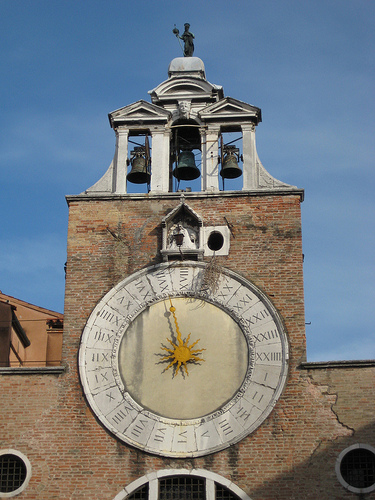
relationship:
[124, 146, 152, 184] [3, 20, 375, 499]
bell on top of building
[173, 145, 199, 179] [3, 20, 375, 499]
bell on top of building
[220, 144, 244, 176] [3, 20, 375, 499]
bell on top of building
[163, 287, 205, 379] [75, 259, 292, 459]
hand on clock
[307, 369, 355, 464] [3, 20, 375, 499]
crack on building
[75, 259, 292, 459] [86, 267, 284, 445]
clock has roman numerals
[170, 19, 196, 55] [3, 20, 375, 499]
statue on top of building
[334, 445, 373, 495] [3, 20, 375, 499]
window in building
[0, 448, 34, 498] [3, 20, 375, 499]
window in building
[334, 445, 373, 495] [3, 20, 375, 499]
window on building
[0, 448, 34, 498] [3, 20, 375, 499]
window on building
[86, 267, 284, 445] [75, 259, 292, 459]
roman numerals on clock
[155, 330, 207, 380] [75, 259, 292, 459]
sun on clock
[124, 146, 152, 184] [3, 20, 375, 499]
bell on building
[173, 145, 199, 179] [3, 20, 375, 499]
bell on building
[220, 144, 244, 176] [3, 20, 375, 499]
bell on building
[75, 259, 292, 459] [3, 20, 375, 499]
clock on building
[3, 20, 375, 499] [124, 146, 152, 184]
building has a bell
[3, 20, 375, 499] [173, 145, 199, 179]
building has a bell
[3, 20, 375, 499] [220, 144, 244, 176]
building has a bell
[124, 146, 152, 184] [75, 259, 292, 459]
bell on top of clock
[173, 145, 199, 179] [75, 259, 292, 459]
bell on top of clock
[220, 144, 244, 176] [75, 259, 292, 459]
bell on top of clock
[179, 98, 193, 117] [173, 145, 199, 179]
face above bell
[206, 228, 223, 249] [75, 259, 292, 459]
hole above clock